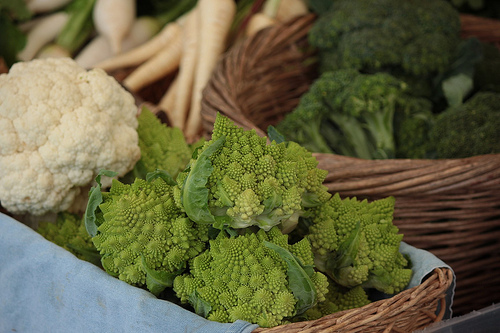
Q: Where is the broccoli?
A: In the basket.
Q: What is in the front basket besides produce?
A: Towel.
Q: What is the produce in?
A: Baskets.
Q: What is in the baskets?
A: Produce.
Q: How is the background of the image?
A: Blur.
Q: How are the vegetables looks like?
A: Fresh.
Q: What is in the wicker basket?
A: Blue cloth.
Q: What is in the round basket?
A: Broccoli.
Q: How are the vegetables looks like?
A: Fresh.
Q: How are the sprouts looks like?
A: Green.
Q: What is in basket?
A: Turnips.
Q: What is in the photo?
A: Food.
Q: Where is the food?
A: In the baskets.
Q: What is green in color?
A: The food.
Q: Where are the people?
A: None in photo.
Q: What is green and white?
A: The food.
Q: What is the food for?
A: Eating.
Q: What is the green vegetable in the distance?
A: Broccoli.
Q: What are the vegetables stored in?
A: Baskets.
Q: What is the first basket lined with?
A: Blue cloth.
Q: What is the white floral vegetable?
A: Cauliflower.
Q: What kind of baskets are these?
A: Wicker.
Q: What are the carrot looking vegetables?
A: Parsnips.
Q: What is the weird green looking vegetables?
A: Cruciferous vegetables.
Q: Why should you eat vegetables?
A: Healthy.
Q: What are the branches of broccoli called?
A: Sprigs.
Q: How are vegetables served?
A: Side dish.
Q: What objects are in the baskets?
A: Vegetables.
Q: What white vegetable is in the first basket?
A: Cauliflower.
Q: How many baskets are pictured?
A: 2.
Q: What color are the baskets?
A: Brown.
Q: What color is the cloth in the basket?
A: Blue.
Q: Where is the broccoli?
A: Top right.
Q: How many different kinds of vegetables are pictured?
A: 5.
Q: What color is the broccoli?
A: Green.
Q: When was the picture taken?
A: Daytime.